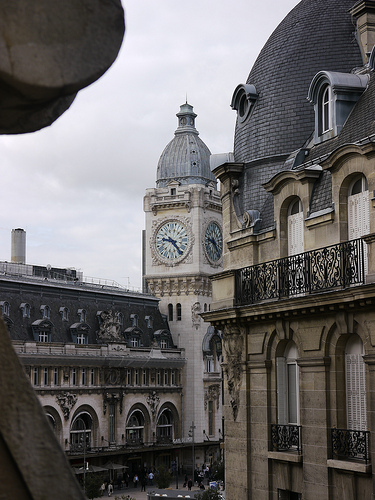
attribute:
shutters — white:
[287, 212, 306, 298]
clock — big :
[149, 214, 195, 267]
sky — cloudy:
[117, 8, 247, 120]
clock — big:
[153, 217, 191, 262]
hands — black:
[161, 229, 183, 257]